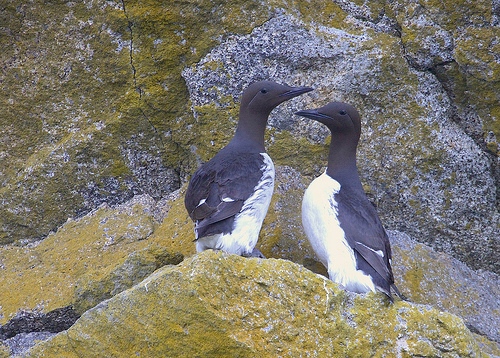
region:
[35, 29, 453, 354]
a scene outside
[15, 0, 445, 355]
a photo during the day time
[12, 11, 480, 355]
a couple of birds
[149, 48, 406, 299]
a gray and white bird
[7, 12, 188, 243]
some green moss on the rock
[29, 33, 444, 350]
two gray and white animals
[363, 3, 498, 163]
a crack in the rock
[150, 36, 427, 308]
two birds standing on a rock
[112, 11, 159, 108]
a crack in the stone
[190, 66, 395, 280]
two birds standing on rocks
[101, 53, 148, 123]
moss is growing on the rocks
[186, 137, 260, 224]
this animal is covered with feathers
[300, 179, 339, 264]
the bird has white feathers on its chest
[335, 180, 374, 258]
the birds wings are black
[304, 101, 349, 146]
the bird has a black head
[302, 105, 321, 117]
the bird has a black beak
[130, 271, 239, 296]
the rocks are gold in color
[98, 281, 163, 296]
the rocks are pointed and sharp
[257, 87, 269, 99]
the bird has black eyes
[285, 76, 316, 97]
bird beak on left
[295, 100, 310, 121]
bird beak on right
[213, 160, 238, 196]
back of bird on left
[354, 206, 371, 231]
back of bird on right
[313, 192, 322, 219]
chest of bird on right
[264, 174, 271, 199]
chest of bird on left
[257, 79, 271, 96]
eye on left bird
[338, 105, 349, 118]
eye on right bird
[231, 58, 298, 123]
head of bird on left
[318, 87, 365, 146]
head of bird on right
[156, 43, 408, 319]
two birds on top of rocks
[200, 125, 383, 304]
two birds on top of rocks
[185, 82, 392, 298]
two birds sitting together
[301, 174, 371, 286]
white patch on the bird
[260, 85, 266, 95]
bird has black eyes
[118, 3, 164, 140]
long crack in the rock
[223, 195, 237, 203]
a white feather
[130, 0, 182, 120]
moss growing on the rock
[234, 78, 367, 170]
birds are looking towards each other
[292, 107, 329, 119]
a black beak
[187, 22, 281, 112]
speckled rock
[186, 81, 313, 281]
bird is sitting on the rock